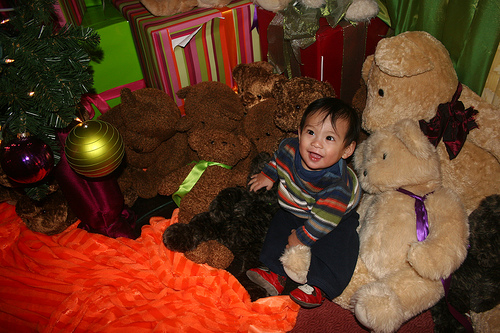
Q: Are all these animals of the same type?
A: Yes, all the animals are bears.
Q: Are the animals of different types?
A: No, all the animals are bears.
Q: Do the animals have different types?
A: No, all the animals are bears.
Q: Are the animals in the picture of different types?
A: No, all the animals are bears.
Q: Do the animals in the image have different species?
A: No, all the animals are bears.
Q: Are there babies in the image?
A: Yes, there is a baby.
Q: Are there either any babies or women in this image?
A: Yes, there is a baby.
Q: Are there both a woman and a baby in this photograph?
A: No, there is a baby but no women.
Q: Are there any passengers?
A: No, there are no passengers.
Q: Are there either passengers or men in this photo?
A: No, there are no passengers or men.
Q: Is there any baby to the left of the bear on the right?
A: Yes, there is a baby to the left of the bear.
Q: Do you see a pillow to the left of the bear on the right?
A: No, there is a baby to the left of the bear.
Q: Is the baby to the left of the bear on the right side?
A: Yes, the baby is to the left of the bear.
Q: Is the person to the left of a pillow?
A: No, the baby is to the left of the bear.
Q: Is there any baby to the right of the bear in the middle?
A: Yes, there is a baby to the right of the bear.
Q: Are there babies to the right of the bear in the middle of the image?
A: Yes, there is a baby to the right of the bear.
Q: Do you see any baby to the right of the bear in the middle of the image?
A: Yes, there is a baby to the right of the bear.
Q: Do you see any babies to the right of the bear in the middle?
A: Yes, there is a baby to the right of the bear.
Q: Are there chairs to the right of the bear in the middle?
A: No, there is a baby to the right of the bear.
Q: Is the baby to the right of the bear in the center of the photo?
A: Yes, the baby is to the right of the bear.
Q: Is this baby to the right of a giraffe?
A: No, the baby is to the right of the bear.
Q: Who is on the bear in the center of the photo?
A: The baby is on the bear.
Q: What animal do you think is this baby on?
A: The baby is on the bear.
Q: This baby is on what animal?
A: The baby is on the bear.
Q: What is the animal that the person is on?
A: The animal is a bear.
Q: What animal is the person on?
A: The baby is on the bear.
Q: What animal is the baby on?
A: The baby is on the bear.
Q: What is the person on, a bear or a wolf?
A: The baby is on a bear.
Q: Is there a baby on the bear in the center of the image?
A: Yes, there is a baby on the bear.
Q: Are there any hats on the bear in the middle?
A: No, there is a baby on the bear.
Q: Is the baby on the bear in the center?
A: Yes, the baby is on the bear.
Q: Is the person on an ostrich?
A: No, the baby is on the bear.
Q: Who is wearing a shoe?
A: The baby is wearing a shoe.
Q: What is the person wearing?
A: The baby is wearing a shoe.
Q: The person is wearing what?
A: The baby is wearing a shoe.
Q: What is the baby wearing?
A: The baby is wearing a shoe.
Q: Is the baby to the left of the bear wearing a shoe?
A: Yes, the baby is wearing a shoe.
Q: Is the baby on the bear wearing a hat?
A: No, the baby is wearing a shoe.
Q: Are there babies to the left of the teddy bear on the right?
A: Yes, there is a baby to the left of the teddy bear.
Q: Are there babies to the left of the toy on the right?
A: Yes, there is a baby to the left of the teddy bear.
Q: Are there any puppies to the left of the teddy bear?
A: No, there is a baby to the left of the teddy bear.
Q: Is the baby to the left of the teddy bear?
A: Yes, the baby is to the left of the teddy bear.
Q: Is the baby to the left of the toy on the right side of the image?
A: Yes, the baby is to the left of the teddy bear.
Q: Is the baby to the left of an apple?
A: No, the baby is to the left of the teddy bear.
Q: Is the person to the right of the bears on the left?
A: Yes, the baby is to the right of the bears.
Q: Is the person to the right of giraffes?
A: No, the baby is to the right of the bears.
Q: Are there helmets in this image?
A: No, there are no helmets.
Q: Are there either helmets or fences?
A: No, there are no helmets or fences.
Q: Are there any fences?
A: No, there are no fences.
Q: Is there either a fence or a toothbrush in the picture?
A: No, there are no fences or toothbrushes.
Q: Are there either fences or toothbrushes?
A: No, there are no fences or toothbrushes.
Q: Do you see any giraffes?
A: No, there are no giraffes.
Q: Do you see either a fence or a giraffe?
A: No, there are no giraffes or fences.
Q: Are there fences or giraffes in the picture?
A: No, there are no giraffes or fences.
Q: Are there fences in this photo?
A: No, there are no fences.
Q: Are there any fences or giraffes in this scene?
A: No, there are no fences or giraffes.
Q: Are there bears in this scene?
A: Yes, there are bears.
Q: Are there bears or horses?
A: Yes, there are bears.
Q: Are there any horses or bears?
A: Yes, there are bears.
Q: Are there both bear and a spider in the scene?
A: No, there are bears but no spiders.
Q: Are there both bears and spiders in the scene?
A: No, there are bears but no spiders.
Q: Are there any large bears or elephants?
A: Yes, there are large bears.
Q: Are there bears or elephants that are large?
A: Yes, the bears are large.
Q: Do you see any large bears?
A: Yes, there are large bears.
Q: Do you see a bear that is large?
A: Yes, there are bears that are large.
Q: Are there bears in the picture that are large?
A: Yes, there are bears that are large.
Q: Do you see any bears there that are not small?
A: Yes, there are large bears.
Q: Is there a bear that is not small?
A: Yes, there are large bears.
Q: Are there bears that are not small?
A: Yes, there are large bears.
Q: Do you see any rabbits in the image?
A: No, there are no rabbits.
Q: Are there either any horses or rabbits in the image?
A: No, there are no rabbits or horses.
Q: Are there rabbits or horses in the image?
A: No, there are no rabbits or horses.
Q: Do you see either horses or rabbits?
A: No, there are no rabbits or horses.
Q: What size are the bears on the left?
A: The bears are large.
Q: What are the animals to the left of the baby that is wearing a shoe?
A: The animals are bears.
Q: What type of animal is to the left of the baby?
A: The animals are bears.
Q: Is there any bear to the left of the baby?
A: Yes, there are bears to the left of the baby.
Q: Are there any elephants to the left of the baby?
A: No, there are bears to the left of the baby.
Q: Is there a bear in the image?
A: Yes, there is a bear.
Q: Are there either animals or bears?
A: Yes, there is a bear.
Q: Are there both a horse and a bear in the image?
A: No, there is a bear but no horses.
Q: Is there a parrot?
A: No, there are no parrots.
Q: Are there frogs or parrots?
A: No, there are no parrots or frogs.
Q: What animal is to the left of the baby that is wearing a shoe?
A: The animal is a bear.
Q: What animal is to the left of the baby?
A: The animal is a bear.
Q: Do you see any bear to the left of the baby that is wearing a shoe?
A: Yes, there is a bear to the left of the baby.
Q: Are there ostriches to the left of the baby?
A: No, there is a bear to the left of the baby.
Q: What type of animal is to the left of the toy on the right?
A: The animal is a bear.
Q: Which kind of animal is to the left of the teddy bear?
A: The animal is a bear.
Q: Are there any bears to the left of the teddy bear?
A: Yes, there is a bear to the left of the teddy bear.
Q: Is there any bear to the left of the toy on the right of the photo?
A: Yes, there is a bear to the left of the teddy bear.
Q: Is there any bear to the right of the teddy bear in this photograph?
A: No, the bear is to the left of the teddy bear.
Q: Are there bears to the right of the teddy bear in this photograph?
A: No, the bear is to the left of the teddy bear.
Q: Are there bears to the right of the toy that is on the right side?
A: No, the bear is to the left of the teddy bear.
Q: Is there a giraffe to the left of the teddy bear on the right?
A: No, there is a bear to the left of the teddy bear.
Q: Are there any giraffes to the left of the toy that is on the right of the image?
A: No, there is a bear to the left of the teddy bear.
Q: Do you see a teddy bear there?
A: Yes, there is a teddy bear.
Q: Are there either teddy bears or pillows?
A: Yes, there is a teddy bear.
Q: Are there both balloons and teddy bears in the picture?
A: No, there is a teddy bear but no balloons.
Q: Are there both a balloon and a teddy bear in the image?
A: No, there is a teddy bear but no balloons.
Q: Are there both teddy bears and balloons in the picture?
A: No, there is a teddy bear but no balloons.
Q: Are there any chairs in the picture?
A: No, there are no chairs.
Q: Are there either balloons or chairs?
A: No, there are no chairs or balloons.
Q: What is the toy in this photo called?
A: The toy is a teddy bear.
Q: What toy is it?
A: The toy is a teddy bear.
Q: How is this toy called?
A: This is a teddy bear.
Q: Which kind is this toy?
A: This is a teddy bear.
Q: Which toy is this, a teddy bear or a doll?
A: This is a teddy bear.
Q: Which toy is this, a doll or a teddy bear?
A: This is a teddy bear.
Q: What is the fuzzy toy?
A: The toy is a teddy bear.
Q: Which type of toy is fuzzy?
A: The toy is a teddy bear.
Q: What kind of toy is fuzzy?
A: The toy is a teddy bear.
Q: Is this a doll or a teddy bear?
A: This is a teddy bear.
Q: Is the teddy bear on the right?
A: Yes, the teddy bear is on the right of the image.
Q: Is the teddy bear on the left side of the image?
A: No, the teddy bear is on the right of the image.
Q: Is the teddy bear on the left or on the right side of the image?
A: The teddy bear is on the right of the image.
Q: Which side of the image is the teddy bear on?
A: The teddy bear is on the right of the image.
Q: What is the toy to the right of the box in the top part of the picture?
A: The toy is a teddy bear.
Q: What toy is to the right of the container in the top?
A: The toy is a teddy bear.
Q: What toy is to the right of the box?
A: The toy is a teddy bear.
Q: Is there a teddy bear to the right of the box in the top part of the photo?
A: Yes, there is a teddy bear to the right of the box.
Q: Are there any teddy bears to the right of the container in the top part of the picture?
A: Yes, there is a teddy bear to the right of the box.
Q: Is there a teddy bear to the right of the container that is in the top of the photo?
A: Yes, there is a teddy bear to the right of the box.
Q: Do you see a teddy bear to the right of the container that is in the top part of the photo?
A: Yes, there is a teddy bear to the right of the box.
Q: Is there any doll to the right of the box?
A: No, there is a teddy bear to the right of the box.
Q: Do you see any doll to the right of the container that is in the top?
A: No, there is a teddy bear to the right of the box.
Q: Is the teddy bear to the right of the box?
A: Yes, the teddy bear is to the right of the box.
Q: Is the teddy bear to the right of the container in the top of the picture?
A: Yes, the teddy bear is to the right of the box.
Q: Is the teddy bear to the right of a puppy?
A: No, the teddy bear is to the right of the box.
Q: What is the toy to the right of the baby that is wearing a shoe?
A: The toy is a teddy bear.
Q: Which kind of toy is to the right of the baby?
A: The toy is a teddy bear.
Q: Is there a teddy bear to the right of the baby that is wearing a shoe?
A: Yes, there is a teddy bear to the right of the baby.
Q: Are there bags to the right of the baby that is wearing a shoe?
A: No, there is a teddy bear to the right of the baby.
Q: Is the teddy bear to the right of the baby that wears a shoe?
A: Yes, the teddy bear is to the right of the baby.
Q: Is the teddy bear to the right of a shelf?
A: No, the teddy bear is to the right of the baby.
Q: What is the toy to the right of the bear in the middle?
A: The toy is a teddy bear.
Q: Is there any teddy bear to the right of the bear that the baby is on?
A: Yes, there is a teddy bear to the right of the bear.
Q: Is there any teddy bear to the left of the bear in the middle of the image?
A: No, the teddy bear is to the right of the bear.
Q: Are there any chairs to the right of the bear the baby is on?
A: No, there is a teddy bear to the right of the bear.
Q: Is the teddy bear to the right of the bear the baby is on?
A: Yes, the teddy bear is to the right of the bear.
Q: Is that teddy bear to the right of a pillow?
A: No, the teddy bear is to the right of the bear.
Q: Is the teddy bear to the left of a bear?
A: No, the teddy bear is to the right of a bear.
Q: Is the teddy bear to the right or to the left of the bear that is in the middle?
A: The teddy bear is to the right of the bear.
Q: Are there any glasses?
A: No, there are no glasses.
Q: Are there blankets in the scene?
A: Yes, there is a blanket.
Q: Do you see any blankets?
A: Yes, there is a blanket.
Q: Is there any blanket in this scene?
A: Yes, there is a blanket.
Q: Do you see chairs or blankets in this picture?
A: Yes, there is a blanket.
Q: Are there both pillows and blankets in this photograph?
A: No, there is a blanket but no pillows.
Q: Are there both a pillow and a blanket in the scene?
A: No, there is a blanket but no pillows.